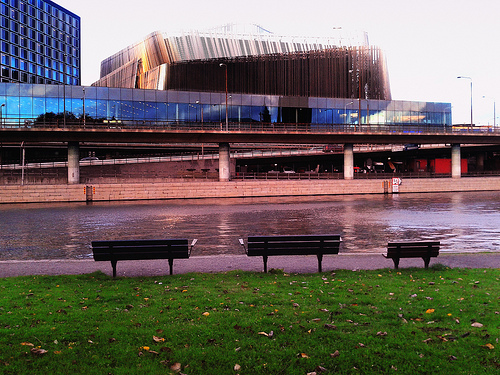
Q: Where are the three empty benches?
A: By the water.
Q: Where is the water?
A: In the canal.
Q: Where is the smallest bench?
A: Last one on the right side.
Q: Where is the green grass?
A: Behind the benches.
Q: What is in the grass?
A: Leaves.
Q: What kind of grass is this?
A: Dark green grass.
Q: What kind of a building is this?
A: Steel and glass building.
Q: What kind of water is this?
A: Light brown water.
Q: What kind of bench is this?
A: A wooden bench.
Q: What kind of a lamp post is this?
A: A dark grey lamp post.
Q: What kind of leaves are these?
A: Fallen leaves.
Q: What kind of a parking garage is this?
A: An underground parking garage.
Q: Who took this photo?
A: Jackson Mingus.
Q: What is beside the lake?
A: A walkway.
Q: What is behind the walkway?
A: Benches.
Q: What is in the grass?
A: Fallen leaves.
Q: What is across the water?
A: A building.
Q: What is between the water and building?
A: A stone wall.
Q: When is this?
A: Daytime.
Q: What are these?
A: Benches.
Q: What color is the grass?
A: Green.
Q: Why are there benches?
A: Sitting.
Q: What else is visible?
A: Buildings.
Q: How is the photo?
A: Clear.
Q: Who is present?
A: Nobody.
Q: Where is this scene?
A: On a canal.